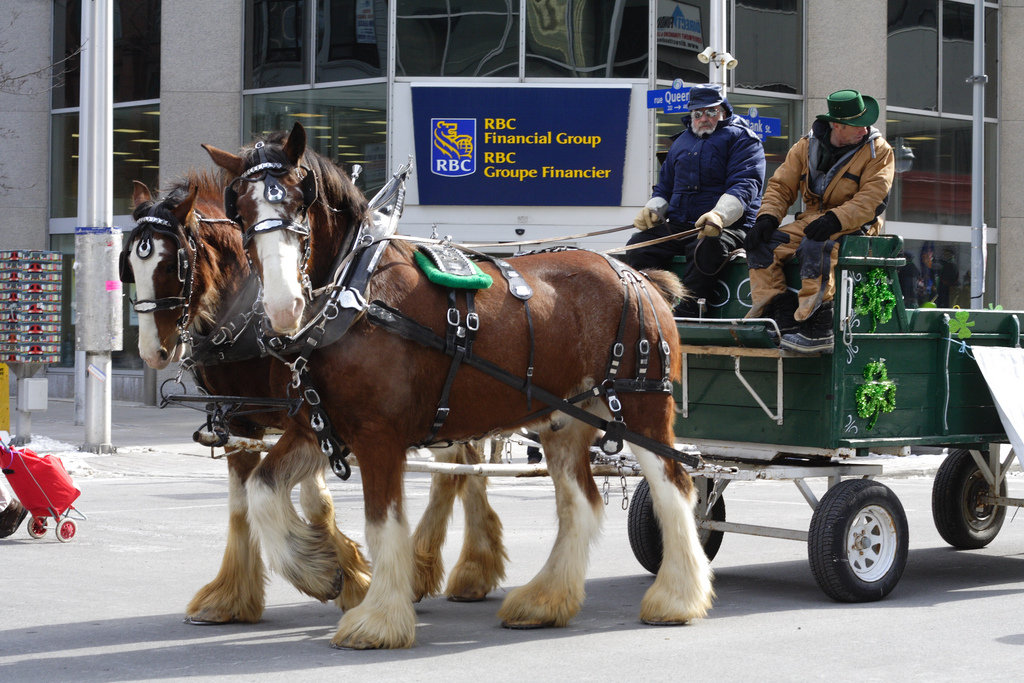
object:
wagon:
[627, 234, 1024, 603]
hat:
[688, 84, 724, 110]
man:
[625, 84, 767, 317]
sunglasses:
[692, 108, 719, 119]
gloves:
[695, 193, 744, 239]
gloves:
[744, 214, 780, 250]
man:
[744, 89, 895, 354]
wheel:
[808, 479, 910, 602]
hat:
[814, 89, 879, 127]